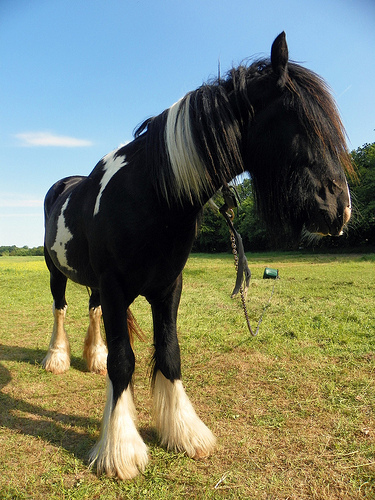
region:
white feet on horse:
[73, 363, 247, 469]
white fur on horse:
[95, 370, 230, 484]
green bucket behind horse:
[258, 255, 308, 290]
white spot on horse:
[49, 193, 97, 263]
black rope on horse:
[208, 174, 309, 349]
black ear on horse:
[259, 27, 305, 77]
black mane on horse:
[187, 89, 264, 176]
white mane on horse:
[166, 104, 222, 179]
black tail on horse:
[127, 310, 149, 342]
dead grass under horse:
[59, 368, 107, 426]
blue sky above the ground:
[89, 52, 126, 79]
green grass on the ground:
[252, 423, 307, 473]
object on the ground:
[258, 258, 288, 285]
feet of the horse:
[112, 401, 208, 450]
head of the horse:
[237, 48, 356, 216]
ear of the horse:
[270, 29, 294, 71]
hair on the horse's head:
[293, 60, 360, 152]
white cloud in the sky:
[40, 110, 85, 149]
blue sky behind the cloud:
[40, 20, 111, 59]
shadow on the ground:
[36, 394, 84, 447]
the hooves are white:
[96, 389, 235, 462]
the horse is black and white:
[35, 132, 372, 365]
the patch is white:
[52, 202, 83, 268]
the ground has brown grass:
[241, 392, 342, 488]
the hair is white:
[155, 100, 224, 178]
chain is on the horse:
[167, 90, 243, 241]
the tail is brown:
[127, 311, 152, 348]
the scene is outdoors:
[6, 9, 370, 491]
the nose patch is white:
[344, 192, 361, 223]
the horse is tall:
[29, 56, 351, 480]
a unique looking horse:
[56, 74, 346, 318]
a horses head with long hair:
[229, 37, 361, 259]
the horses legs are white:
[75, 329, 241, 491]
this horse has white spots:
[47, 159, 137, 280]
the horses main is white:
[146, 99, 208, 210]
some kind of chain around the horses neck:
[210, 174, 257, 307]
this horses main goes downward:
[159, 63, 347, 201]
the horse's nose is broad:
[288, 162, 354, 246]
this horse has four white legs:
[47, 291, 218, 488]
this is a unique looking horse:
[42, 47, 332, 319]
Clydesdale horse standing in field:
[35, 67, 352, 489]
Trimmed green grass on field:
[14, 254, 372, 492]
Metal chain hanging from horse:
[217, 221, 262, 317]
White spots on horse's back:
[47, 182, 96, 269]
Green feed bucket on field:
[262, 254, 294, 278]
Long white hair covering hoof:
[70, 412, 162, 498]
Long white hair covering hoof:
[147, 376, 219, 489]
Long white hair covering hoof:
[31, 315, 73, 384]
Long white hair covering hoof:
[75, 313, 111, 384]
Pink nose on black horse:
[332, 203, 367, 227]